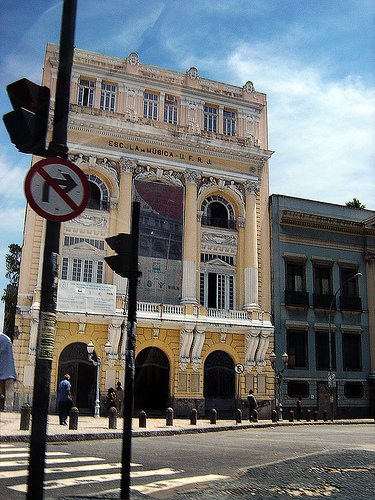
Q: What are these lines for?
A: A cross walk.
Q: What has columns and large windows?
A: Large cream colored building.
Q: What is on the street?
A: The cross walk.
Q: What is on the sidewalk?
A: The roadblocks.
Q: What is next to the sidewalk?
A: The light colored building.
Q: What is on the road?
A: White lines.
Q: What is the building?
A: Yellow.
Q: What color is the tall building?
A: Yellow.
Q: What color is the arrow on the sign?
A: Black.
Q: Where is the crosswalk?
A: Lower left corner.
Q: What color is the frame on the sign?
A: Red.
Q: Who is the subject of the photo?
A: The building.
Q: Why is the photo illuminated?
A: Sunlight.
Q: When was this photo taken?
A: During the day.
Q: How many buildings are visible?
A: 2.